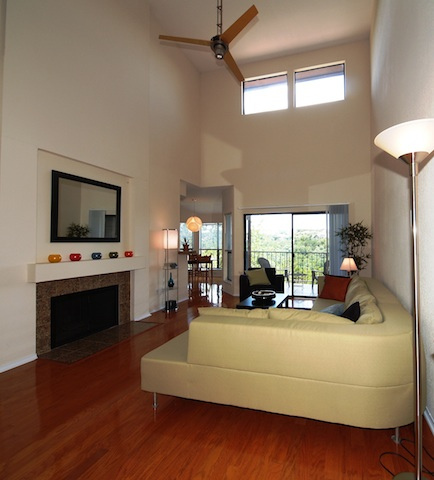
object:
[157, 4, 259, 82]
ceiling fan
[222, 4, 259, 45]
blade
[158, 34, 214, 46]
blade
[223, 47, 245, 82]
blade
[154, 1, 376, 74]
ceiling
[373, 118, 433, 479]
floor lamp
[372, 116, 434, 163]
lamp shade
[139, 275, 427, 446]
sectional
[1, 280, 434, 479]
floor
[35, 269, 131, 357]
fire place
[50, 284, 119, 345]
screen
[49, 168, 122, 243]
mirror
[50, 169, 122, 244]
frame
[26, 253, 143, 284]
mantel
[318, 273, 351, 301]
pillow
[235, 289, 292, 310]
coffee table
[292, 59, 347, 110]
window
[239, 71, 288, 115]
window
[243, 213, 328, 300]
sliding door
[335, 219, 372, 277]
plant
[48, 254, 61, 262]
candle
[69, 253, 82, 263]
candle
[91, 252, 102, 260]
candle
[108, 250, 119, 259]
candle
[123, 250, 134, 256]
candle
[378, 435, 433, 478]
cord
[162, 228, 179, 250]
lamp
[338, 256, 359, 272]
lamp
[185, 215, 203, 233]
light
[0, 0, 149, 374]
wall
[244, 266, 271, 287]
pillow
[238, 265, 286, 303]
chair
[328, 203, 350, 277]
curtain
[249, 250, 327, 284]
railing